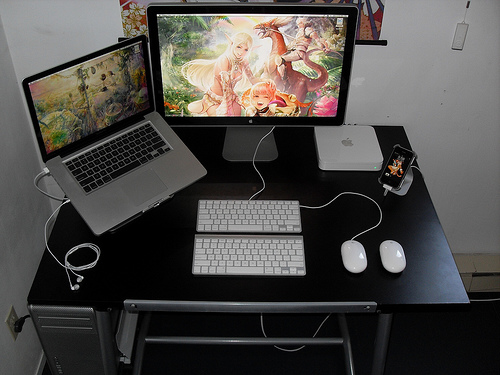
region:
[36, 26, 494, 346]
Picture is taken indoors.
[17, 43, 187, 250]
A laptop is on a computer desk.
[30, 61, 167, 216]
The laptop is a Apple.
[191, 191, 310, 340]
Two keyboards are on the desk.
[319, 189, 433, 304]
Two computer mice are on the desk.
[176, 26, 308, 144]
The apple monitor is on.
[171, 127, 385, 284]
The desktop is black in color.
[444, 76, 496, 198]
The wall is painted white.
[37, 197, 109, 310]
Earbuds are sticking out of the laptop.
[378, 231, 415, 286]
A wireless mouse is on the desk.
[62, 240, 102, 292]
ear buds for a computer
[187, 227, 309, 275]
a grey keyboard in a desk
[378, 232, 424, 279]
a wireless computer mouse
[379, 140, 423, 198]
a cell phone on a charger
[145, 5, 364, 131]
a flat screen computer moniter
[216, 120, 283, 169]
base of a moniter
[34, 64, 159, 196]
a grey and black laptom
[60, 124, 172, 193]
black key of a laptop keyboard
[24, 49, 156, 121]
a moniter of a laptop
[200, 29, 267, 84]
a girl's photo on a computer monitor screen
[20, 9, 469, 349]
A computer desk and setup is shown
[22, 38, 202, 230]
This is a laptop computer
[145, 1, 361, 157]
This is a desk top computer monitor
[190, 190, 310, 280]
These are keyboards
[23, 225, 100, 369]
This is a computer tower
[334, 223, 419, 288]
Two computer mice are here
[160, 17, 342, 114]
A fantasy scene is used as wallpaper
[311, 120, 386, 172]
This is a wireless router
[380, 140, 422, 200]
A smart phone is connected here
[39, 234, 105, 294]
These are ear bud headphones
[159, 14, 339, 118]
Colorful wallpaper on computer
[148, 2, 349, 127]
The monitor is a Mac monitor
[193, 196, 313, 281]
Two mac keyboards on table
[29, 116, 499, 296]
Table is black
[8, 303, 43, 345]
One plug connected to the outlet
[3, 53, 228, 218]
Mac laptop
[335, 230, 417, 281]
Two mouses are by the keyboard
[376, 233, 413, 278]
One of the mouses is not connected to anything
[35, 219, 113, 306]
Silver earphones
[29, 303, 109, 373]
The table is made of steal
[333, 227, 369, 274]
A corded mouse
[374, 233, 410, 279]
A cordless mouse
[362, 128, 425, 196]
A phone charging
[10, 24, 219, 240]
A laptop sitting on the corner of the desk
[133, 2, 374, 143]
Monitor sitting on a desk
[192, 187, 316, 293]
Two keyboards sitting together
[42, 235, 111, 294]
Earphone plugged into the computer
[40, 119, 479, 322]
A black desk in the corner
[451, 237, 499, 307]
A wall heater on the floor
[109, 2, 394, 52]
A picture on the wall behind the desk